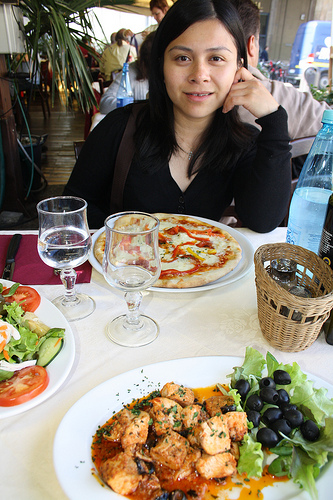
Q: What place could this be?
A: It is a restaurant.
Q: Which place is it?
A: It is a restaurant.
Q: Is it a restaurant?
A: Yes, it is a restaurant.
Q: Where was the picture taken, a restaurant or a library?
A: It was taken at a restaurant.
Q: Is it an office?
A: No, it is a restaurant.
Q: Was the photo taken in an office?
A: No, the picture was taken in a restaurant.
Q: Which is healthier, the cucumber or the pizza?
A: The cucumber is healthier than the pizza.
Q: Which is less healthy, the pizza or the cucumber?
A: The pizza is less healthy than the cucumber.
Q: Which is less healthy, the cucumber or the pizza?
A: The pizza is less healthy than the cucumber.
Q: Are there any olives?
A: Yes, there are olives.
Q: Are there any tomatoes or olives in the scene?
A: Yes, there are olives.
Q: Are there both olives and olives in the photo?
A: Yes, there are both olives and an olive.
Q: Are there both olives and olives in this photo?
A: Yes, there are both olives and an olive.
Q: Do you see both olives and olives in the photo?
A: Yes, there are both olives and an olive.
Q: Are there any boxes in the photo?
A: No, there are no boxes.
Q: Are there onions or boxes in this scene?
A: No, there are no boxes or onions.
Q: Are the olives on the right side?
A: Yes, the olives are on the right of the image.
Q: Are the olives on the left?
A: No, the olives are on the right of the image.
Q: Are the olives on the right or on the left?
A: The olives are on the right of the image.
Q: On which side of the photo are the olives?
A: The olives are on the right of the image.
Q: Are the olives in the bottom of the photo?
A: Yes, the olives are in the bottom of the image.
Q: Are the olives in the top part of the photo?
A: No, the olives are in the bottom of the image.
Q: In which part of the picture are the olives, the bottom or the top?
A: The olives are in the bottom of the image.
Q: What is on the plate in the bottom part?
A: The olives are on the plate.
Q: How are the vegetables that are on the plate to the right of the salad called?
A: The vegetables are olives.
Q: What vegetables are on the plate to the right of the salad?
A: The vegetables are olives.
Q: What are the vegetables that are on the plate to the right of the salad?
A: The vegetables are olives.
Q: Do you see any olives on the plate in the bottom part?
A: Yes, there are olives on the plate.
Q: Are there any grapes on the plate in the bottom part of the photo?
A: No, there are olives on the plate.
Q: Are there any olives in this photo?
A: Yes, there are olives.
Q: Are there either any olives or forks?
A: Yes, there are olives.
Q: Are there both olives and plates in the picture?
A: Yes, there are both olives and a plate.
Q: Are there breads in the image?
A: No, there are no breads.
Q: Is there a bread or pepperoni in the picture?
A: No, there are no breads or pepperoni.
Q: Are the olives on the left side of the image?
A: No, the olives are on the right of the image.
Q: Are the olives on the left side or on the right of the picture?
A: The olives are on the right of the image.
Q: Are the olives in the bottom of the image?
A: Yes, the olives are in the bottom of the image.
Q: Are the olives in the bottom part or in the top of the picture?
A: The olives are in the bottom of the image.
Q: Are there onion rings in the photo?
A: No, there are no onion rings.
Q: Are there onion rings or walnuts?
A: No, there are no onion rings or walnuts.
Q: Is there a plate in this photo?
A: Yes, there is a plate.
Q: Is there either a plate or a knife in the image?
A: Yes, there is a plate.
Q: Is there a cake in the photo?
A: No, there are no cakes.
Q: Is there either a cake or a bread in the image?
A: No, there are no cakes or breads.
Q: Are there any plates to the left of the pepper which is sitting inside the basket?
A: Yes, there is a plate to the left of the pepper.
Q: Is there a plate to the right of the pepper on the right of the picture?
A: No, the plate is to the left of the pepper.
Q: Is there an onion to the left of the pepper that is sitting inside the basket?
A: No, there is a plate to the left of the pepper.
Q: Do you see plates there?
A: Yes, there is a plate.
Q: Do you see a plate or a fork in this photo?
A: Yes, there is a plate.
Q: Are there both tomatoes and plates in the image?
A: Yes, there are both a plate and a tomato.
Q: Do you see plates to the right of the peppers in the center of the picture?
A: Yes, there is a plate to the right of the peppers.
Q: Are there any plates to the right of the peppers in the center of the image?
A: Yes, there is a plate to the right of the peppers.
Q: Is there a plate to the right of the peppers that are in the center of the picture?
A: Yes, there is a plate to the right of the peppers.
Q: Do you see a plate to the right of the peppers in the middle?
A: Yes, there is a plate to the right of the peppers.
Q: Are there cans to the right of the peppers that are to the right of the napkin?
A: No, there is a plate to the right of the peppers.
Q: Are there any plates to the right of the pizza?
A: Yes, there is a plate to the right of the pizza.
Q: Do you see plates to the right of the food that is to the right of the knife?
A: Yes, there is a plate to the right of the pizza.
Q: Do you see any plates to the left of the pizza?
A: No, the plate is to the right of the pizza.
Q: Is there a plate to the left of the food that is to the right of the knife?
A: No, the plate is to the right of the pizza.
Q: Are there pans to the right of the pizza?
A: No, there is a plate to the right of the pizza.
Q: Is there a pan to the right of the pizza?
A: No, there is a plate to the right of the pizza.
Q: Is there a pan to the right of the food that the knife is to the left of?
A: No, there is a plate to the right of the pizza.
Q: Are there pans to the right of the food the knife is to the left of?
A: No, there is a plate to the right of the pizza.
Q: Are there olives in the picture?
A: Yes, there are olives.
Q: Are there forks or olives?
A: Yes, there are olives.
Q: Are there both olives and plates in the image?
A: Yes, there are both olives and a plate.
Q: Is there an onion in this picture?
A: No, there are no onions.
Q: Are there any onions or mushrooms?
A: No, there are no onions or mushrooms.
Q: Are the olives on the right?
A: Yes, the olives are on the right of the image.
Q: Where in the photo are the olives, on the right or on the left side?
A: The olives are on the right of the image.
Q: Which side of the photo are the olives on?
A: The olives are on the right of the image.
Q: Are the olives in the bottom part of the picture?
A: Yes, the olives are in the bottom of the image.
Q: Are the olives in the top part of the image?
A: No, the olives are in the bottom of the image.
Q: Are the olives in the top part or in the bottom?
A: The olives are in the bottom of the image.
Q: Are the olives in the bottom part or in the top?
A: The olives are in the bottom of the image.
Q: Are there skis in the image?
A: No, there are no skis.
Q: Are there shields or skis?
A: No, there are no skis or shields.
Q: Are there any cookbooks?
A: No, there are no cookbooks.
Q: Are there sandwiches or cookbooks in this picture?
A: No, there are no cookbooks or sandwiches.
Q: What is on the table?
A: The chicken is on the table.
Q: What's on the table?
A: The chicken is on the table.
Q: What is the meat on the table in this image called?
A: The meat is chicken.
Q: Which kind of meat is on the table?
A: The meat is chicken.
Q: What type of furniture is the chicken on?
A: The chicken is on the table.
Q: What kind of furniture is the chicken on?
A: The chicken is on the table.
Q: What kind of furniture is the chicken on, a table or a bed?
A: The chicken is on a table.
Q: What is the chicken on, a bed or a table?
A: The chicken is on a table.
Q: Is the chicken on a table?
A: Yes, the chicken is on a table.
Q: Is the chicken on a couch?
A: No, the chicken is on a table.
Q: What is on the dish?
A: The chicken is on the dish.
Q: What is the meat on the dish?
A: The meat is chicken.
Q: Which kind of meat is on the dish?
A: The meat is chicken.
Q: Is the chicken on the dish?
A: Yes, the chicken is on the dish.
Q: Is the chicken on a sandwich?
A: No, the chicken is on the dish.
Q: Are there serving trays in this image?
A: No, there are no serving trays.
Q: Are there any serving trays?
A: No, there are no serving trays.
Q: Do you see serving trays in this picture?
A: No, there are no serving trays.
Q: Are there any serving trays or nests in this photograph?
A: No, there are no serving trays or nests.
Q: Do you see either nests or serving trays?
A: No, there are no serving trays or nests.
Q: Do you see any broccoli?
A: No, there is no broccoli.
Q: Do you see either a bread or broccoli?
A: No, there are no broccoli or breads.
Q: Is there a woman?
A: Yes, there is a woman.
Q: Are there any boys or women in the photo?
A: Yes, there is a woman.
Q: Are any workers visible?
A: No, there are no workers.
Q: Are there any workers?
A: No, there are no workers.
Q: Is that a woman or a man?
A: That is a woman.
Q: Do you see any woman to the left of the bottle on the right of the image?
A: Yes, there is a woman to the left of the bottle.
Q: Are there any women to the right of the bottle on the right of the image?
A: No, the woman is to the left of the bottle.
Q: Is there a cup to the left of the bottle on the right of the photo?
A: No, there is a woman to the left of the bottle.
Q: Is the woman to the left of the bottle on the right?
A: Yes, the woman is to the left of the bottle.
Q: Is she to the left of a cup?
A: No, the woman is to the left of the bottle.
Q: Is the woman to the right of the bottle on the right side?
A: No, the woman is to the left of the bottle.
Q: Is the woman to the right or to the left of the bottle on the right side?
A: The woman is to the left of the bottle.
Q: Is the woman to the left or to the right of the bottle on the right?
A: The woman is to the left of the bottle.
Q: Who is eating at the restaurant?
A: The woman is eating at the restaurant.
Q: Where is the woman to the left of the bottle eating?
A: The woman is eating at the restaurant.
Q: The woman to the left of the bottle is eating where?
A: The woman is eating at the restaurant.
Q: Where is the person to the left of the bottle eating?
A: The woman is eating at the restaurant.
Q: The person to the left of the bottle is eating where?
A: The woman is eating at the restaurant.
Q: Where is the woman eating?
A: The woman is eating at the restaurant.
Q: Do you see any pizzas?
A: Yes, there is a pizza.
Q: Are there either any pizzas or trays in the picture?
A: Yes, there is a pizza.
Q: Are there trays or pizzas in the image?
A: Yes, there is a pizza.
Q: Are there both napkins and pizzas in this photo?
A: Yes, there are both a pizza and a napkin.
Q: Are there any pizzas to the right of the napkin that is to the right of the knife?
A: Yes, there is a pizza to the right of the napkin.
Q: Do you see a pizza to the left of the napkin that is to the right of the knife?
A: No, the pizza is to the right of the napkin.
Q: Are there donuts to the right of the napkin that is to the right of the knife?
A: No, there is a pizza to the right of the napkin.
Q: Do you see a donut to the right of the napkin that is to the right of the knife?
A: No, there is a pizza to the right of the napkin.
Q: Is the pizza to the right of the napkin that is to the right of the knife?
A: Yes, the pizza is to the right of the napkin.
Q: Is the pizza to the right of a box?
A: No, the pizza is to the right of the napkin.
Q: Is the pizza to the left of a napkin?
A: No, the pizza is to the right of a napkin.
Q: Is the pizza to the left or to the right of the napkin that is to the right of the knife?
A: The pizza is to the right of the napkin.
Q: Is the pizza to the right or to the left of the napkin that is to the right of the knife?
A: The pizza is to the right of the napkin.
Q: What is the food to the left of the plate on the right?
A: The food is a pizza.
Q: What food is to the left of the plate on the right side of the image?
A: The food is a pizza.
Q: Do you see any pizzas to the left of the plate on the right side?
A: Yes, there is a pizza to the left of the plate.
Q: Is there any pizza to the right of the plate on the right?
A: No, the pizza is to the left of the plate.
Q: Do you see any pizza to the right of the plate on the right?
A: No, the pizza is to the left of the plate.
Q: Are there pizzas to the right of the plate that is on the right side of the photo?
A: No, the pizza is to the left of the plate.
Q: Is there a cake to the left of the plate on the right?
A: No, there is a pizza to the left of the plate.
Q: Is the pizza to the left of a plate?
A: Yes, the pizza is to the left of a plate.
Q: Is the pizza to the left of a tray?
A: No, the pizza is to the left of a plate.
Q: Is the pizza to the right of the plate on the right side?
A: No, the pizza is to the left of the plate.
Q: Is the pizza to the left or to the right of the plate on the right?
A: The pizza is to the left of the plate.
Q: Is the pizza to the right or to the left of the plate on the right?
A: The pizza is to the left of the plate.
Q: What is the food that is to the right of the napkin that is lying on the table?
A: The food is a pizza.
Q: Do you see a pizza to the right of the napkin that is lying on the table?
A: Yes, there is a pizza to the right of the napkin.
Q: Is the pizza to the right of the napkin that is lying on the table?
A: Yes, the pizza is to the right of the napkin.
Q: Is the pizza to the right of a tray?
A: No, the pizza is to the right of the napkin.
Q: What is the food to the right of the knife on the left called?
A: The food is a pizza.